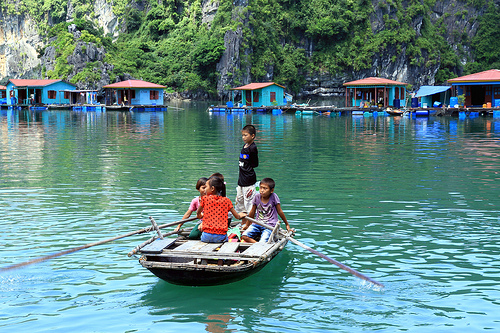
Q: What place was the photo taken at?
A: It was taken at the river.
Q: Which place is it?
A: It is a river.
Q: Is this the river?
A: Yes, it is the river.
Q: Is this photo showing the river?
A: Yes, it is showing the river.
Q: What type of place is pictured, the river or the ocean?
A: It is the river.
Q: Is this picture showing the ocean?
A: No, the picture is showing the river.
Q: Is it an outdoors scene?
A: Yes, it is outdoors.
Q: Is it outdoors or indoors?
A: It is outdoors.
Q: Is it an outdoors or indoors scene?
A: It is outdoors.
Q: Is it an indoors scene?
A: No, it is outdoors.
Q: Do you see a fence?
A: No, there are no fences.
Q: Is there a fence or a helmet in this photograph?
A: No, there are no fences or helmets.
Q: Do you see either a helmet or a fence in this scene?
A: No, there are no fences or helmets.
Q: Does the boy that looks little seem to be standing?
A: Yes, the boy is standing.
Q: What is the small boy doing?
A: The boy is standing.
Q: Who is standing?
A: The boy is standing.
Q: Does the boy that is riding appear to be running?
A: No, the boy is standing.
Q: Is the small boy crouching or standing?
A: The boy is standing.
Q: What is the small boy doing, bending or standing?
A: The boy is standing.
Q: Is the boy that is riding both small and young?
A: Yes, the boy is small and young.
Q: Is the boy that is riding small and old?
A: No, the boy is small but young.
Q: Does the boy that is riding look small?
A: Yes, the boy is small.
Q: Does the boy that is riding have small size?
A: Yes, the boy is small.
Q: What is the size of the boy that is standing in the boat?
A: The boy is small.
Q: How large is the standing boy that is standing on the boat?
A: The boy is small.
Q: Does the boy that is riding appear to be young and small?
A: Yes, the boy is young and small.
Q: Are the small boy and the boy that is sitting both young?
A: Yes, both the boy and the boy are young.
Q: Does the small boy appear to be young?
A: Yes, the boy is young.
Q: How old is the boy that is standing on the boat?
A: The boy is young.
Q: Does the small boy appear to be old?
A: No, the boy is young.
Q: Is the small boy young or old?
A: The boy is young.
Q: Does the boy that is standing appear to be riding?
A: Yes, the boy is riding.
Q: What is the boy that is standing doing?
A: The boy is riding.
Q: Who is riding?
A: The boy is riding.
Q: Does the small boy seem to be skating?
A: No, the boy is riding.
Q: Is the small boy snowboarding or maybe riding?
A: The boy is riding.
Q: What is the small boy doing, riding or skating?
A: The boy is riding.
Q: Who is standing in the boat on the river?
A: The boy is standing in the boat.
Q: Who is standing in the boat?
A: The boy is standing in the boat.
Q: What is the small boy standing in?
A: The boy is standing in the boat.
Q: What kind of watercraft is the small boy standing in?
A: The boy is standing in the boat.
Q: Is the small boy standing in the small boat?
A: Yes, the boy is standing in the boat.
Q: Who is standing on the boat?
A: The boy is standing on the boat.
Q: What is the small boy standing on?
A: The boy is standing on the boat.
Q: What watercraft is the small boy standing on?
A: The boy is standing on the boat.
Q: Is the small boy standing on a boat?
A: Yes, the boy is standing on a boat.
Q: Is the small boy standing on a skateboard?
A: No, the boy is standing on a boat.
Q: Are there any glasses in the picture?
A: No, there are no glasses.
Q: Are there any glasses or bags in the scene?
A: No, there are no glasses or bags.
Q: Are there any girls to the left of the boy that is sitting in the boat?
A: Yes, there is a girl to the left of the boy.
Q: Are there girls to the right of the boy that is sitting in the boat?
A: No, the girl is to the left of the boy.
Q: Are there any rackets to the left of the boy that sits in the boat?
A: No, there is a girl to the left of the boy.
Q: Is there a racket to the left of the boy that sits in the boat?
A: No, there is a girl to the left of the boy.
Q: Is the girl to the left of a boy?
A: Yes, the girl is to the left of a boy.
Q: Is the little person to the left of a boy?
A: Yes, the girl is to the left of a boy.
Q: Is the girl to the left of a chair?
A: No, the girl is to the left of a boy.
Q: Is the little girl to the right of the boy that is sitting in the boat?
A: No, the girl is to the left of the boy.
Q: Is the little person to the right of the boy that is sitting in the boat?
A: No, the girl is to the left of the boy.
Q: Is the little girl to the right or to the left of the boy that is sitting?
A: The girl is to the left of the boy.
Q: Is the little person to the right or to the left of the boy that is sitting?
A: The girl is to the left of the boy.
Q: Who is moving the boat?
A: The girl is moving the boat.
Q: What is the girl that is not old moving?
A: The girl is moving the boat.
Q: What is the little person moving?
A: The girl is moving the boat.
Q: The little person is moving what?
A: The girl is moving the boat.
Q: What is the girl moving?
A: The girl is moving the boat.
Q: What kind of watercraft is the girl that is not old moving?
A: The girl is moving the boat.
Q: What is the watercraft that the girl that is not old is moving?
A: The watercraft is a boat.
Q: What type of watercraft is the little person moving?
A: The girl is moving the boat.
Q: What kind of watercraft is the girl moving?
A: The girl is moving the boat.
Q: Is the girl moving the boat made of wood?
A: Yes, the girl is moving the boat.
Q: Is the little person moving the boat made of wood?
A: Yes, the girl is moving the boat.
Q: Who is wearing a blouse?
A: The girl is wearing a blouse.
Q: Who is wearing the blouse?
A: The girl is wearing a blouse.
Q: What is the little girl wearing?
A: The girl is wearing a blouse.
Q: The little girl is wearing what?
A: The girl is wearing a blouse.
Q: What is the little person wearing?
A: The girl is wearing a blouse.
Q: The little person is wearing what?
A: The girl is wearing a blouse.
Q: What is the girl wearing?
A: The girl is wearing a blouse.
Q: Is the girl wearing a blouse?
A: Yes, the girl is wearing a blouse.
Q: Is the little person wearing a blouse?
A: Yes, the girl is wearing a blouse.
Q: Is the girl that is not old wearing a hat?
A: No, the girl is wearing a blouse.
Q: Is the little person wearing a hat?
A: No, the girl is wearing a blouse.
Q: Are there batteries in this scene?
A: No, there are no batteries.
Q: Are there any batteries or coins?
A: No, there are no batteries or coins.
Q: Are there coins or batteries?
A: No, there are no batteries or coins.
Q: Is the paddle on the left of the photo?
A: Yes, the paddle is on the left of the image.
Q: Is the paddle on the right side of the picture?
A: No, the paddle is on the left of the image.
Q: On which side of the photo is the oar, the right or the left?
A: The oar is on the left of the image.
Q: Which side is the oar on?
A: The oar is on the left of the image.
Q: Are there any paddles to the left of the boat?
A: Yes, there is a paddle to the left of the boat.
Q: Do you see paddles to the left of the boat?
A: Yes, there is a paddle to the left of the boat.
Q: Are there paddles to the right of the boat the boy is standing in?
A: No, the paddle is to the left of the boat.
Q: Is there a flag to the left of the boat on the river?
A: No, there is a paddle to the left of the boat.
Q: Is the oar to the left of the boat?
A: Yes, the oar is to the left of the boat.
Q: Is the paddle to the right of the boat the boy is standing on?
A: No, the paddle is to the left of the boat.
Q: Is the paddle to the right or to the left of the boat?
A: The paddle is to the left of the boat.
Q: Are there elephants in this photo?
A: No, there are no elephants.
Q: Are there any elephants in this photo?
A: No, there are no elephants.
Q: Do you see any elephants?
A: No, there are no elephants.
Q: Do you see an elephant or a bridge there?
A: No, there are no elephants or bridges.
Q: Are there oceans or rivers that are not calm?
A: No, there is a river but it is calm.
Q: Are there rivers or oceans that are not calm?
A: No, there is a river but it is calm.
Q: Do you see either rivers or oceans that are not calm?
A: No, there is a river but it is calm.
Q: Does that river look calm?
A: Yes, the river is calm.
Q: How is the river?
A: The river is calm.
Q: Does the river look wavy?
A: No, the river is calm.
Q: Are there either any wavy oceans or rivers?
A: No, there is a river but it is calm.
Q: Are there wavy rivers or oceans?
A: No, there is a river but it is calm.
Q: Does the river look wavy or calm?
A: The river is calm.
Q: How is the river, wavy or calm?
A: The river is calm.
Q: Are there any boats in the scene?
A: Yes, there is a boat.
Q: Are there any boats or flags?
A: Yes, there is a boat.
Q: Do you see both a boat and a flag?
A: No, there is a boat but no flags.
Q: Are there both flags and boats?
A: No, there is a boat but no flags.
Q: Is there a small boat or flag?
A: Yes, there is a small boat.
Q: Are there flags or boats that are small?
A: Yes, the boat is small.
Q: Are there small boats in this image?
A: Yes, there is a small boat.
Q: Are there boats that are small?
A: Yes, there is a boat that is small.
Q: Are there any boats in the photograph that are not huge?
A: Yes, there is a small boat.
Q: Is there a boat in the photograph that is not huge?
A: Yes, there is a small boat.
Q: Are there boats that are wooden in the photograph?
A: Yes, there is a wood boat.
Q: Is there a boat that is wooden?
A: Yes, there is a boat that is wooden.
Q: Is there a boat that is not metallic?
A: Yes, there is a wooden boat.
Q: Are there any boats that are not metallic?
A: Yes, there is a wooden boat.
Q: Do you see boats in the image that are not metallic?
A: Yes, there is a wooden boat.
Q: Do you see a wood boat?
A: Yes, there is a boat that is made of wood.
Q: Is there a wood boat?
A: Yes, there is a boat that is made of wood.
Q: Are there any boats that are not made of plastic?
A: Yes, there is a boat that is made of wood.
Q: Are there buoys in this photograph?
A: No, there are no buoys.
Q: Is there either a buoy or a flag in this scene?
A: No, there are no buoys or flags.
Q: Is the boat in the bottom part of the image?
A: Yes, the boat is in the bottom of the image.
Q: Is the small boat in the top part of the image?
A: No, the boat is in the bottom of the image.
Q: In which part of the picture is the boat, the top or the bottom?
A: The boat is in the bottom of the image.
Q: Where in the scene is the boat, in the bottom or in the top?
A: The boat is in the bottom of the image.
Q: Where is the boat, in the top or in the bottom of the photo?
A: The boat is in the bottom of the image.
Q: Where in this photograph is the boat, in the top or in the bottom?
A: The boat is in the bottom of the image.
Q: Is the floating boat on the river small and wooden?
A: Yes, the boat is small and wooden.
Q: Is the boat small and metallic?
A: No, the boat is small but wooden.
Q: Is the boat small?
A: Yes, the boat is small.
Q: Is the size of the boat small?
A: Yes, the boat is small.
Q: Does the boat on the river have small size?
A: Yes, the boat is small.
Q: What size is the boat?
A: The boat is small.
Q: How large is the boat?
A: The boat is small.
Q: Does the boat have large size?
A: No, the boat is small.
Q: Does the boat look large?
A: No, the boat is small.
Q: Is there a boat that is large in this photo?
A: No, there is a boat but it is small.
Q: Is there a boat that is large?
A: No, there is a boat but it is small.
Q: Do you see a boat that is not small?
A: No, there is a boat but it is small.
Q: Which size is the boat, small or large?
A: The boat is small.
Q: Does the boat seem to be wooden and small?
A: Yes, the boat is wooden and small.